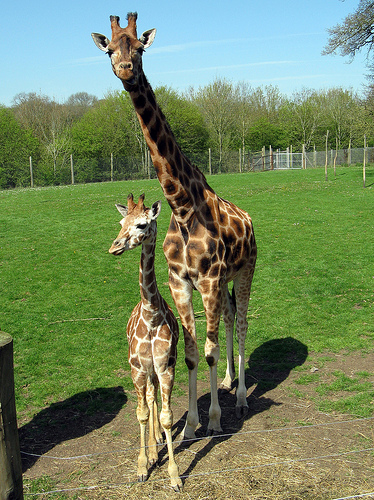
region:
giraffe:
[0, 160, 132, 459]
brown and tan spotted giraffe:
[89, 179, 199, 496]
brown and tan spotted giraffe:
[93, 15, 288, 457]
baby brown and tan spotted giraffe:
[73, 160, 208, 483]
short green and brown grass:
[14, 185, 76, 227]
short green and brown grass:
[23, 241, 91, 289]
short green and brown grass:
[0, 289, 83, 326]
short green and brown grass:
[40, 328, 114, 383]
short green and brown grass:
[56, 405, 111, 459]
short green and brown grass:
[289, 364, 360, 438]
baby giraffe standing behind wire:
[98, 189, 196, 487]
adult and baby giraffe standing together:
[82, 9, 276, 489]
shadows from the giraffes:
[131, 299, 317, 487]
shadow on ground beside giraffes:
[17, 369, 125, 490]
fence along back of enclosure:
[30, 143, 362, 190]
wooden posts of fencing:
[24, 147, 368, 176]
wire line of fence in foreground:
[18, 417, 372, 498]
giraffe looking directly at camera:
[93, 7, 288, 446]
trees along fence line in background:
[14, 65, 359, 165]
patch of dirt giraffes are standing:
[41, 342, 363, 499]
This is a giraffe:
[98, 183, 184, 497]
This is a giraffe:
[86, 11, 278, 455]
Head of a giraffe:
[91, 172, 162, 268]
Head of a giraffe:
[87, 10, 161, 90]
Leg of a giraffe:
[198, 271, 231, 445]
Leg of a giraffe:
[162, 262, 206, 442]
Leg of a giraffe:
[154, 357, 188, 493]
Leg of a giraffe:
[125, 357, 154, 488]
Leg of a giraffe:
[142, 365, 160, 475]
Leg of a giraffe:
[234, 264, 258, 416]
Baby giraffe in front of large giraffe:
[105, 189, 185, 493]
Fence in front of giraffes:
[0, 326, 372, 498]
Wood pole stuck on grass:
[361, 131, 369, 190]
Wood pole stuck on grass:
[320, 127, 331, 179]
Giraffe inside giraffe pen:
[91, 11, 258, 436]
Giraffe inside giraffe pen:
[108, 193, 183, 491]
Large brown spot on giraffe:
[199, 196, 218, 222]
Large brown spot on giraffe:
[228, 213, 244, 237]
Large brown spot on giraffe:
[133, 318, 149, 338]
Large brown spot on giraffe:
[161, 178, 177, 198]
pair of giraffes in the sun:
[91, 14, 258, 483]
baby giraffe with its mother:
[89, 9, 257, 404]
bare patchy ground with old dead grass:
[77, 395, 339, 489]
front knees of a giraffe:
[134, 401, 173, 428]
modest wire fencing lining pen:
[60, 424, 333, 498]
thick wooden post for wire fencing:
[1, 330, 27, 498]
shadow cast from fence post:
[25, 388, 124, 437]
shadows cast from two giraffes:
[168, 321, 298, 432]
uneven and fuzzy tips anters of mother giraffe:
[107, 9, 138, 34]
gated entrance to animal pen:
[265, 148, 308, 167]